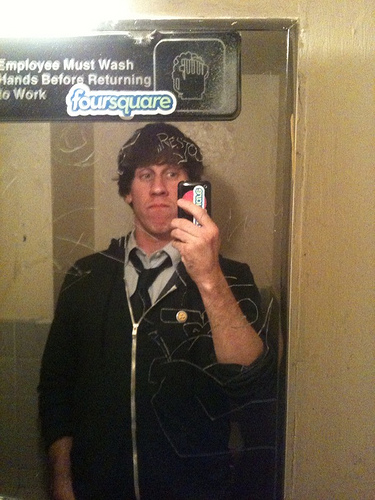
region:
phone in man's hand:
[163, 165, 234, 240]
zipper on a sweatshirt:
[118, 320, 153, 486]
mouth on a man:
[142, 201, 175, 217]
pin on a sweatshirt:
[169, 297, 185, 327]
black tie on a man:
[124, 248, 164, 323]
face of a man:
[111, 120, 203, 248]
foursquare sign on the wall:
[66, 70, 177, 130]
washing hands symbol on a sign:
[159, 47, 211, 100]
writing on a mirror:
[153, 124, 206, 169]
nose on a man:
[146, 177, 169, 194]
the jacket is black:
[53, 252, 246, 456]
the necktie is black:
[117, 237, 168, 344]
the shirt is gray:
[116, 241, 192, 347]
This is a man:
[49, 129, 285, 453]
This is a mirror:
[60, 267, 234, 479]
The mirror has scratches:
[148, 331, 285, 483]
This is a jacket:
[71, 302, 232, 479]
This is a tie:
[123, 219, 189, 294]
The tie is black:
[149, 261, 152, 308]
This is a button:
[119, 285, 193, 336]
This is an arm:
[149, 264, 312, 365]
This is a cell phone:
[148, 168, 219, 257]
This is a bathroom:
[30, 306, 262, 479]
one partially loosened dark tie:
[123, 244, 174, 323]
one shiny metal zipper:
[125, 309, 145, 499]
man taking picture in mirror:
[38, 127, 274, 457]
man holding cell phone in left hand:
[93, 121, 259, 364]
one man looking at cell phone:
[114, 123, 221, 266]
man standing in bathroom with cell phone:
[8, 125, 282, 495]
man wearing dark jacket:
[38, 123, 272, 426]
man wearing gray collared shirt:
[81, 123, 247, 327]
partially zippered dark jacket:
[42, 239, 268, 488]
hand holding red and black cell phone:
[170, 177, 262, 374]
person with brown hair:
[30, 114, 290, 498]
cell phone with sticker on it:
[171, 176, 222, 230]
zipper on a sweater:
[124, 318, 143, 499]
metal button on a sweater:
[173, 305, 192, 331]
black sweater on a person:
[30, 226, 271, 498]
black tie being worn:
[122, 246, 175, 321]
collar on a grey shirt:
[118, 229, 189, 271]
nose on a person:
[147, 174, 170, 200]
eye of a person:
[160, 165, 179, 181]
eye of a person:
[138, 166, 156, 185]